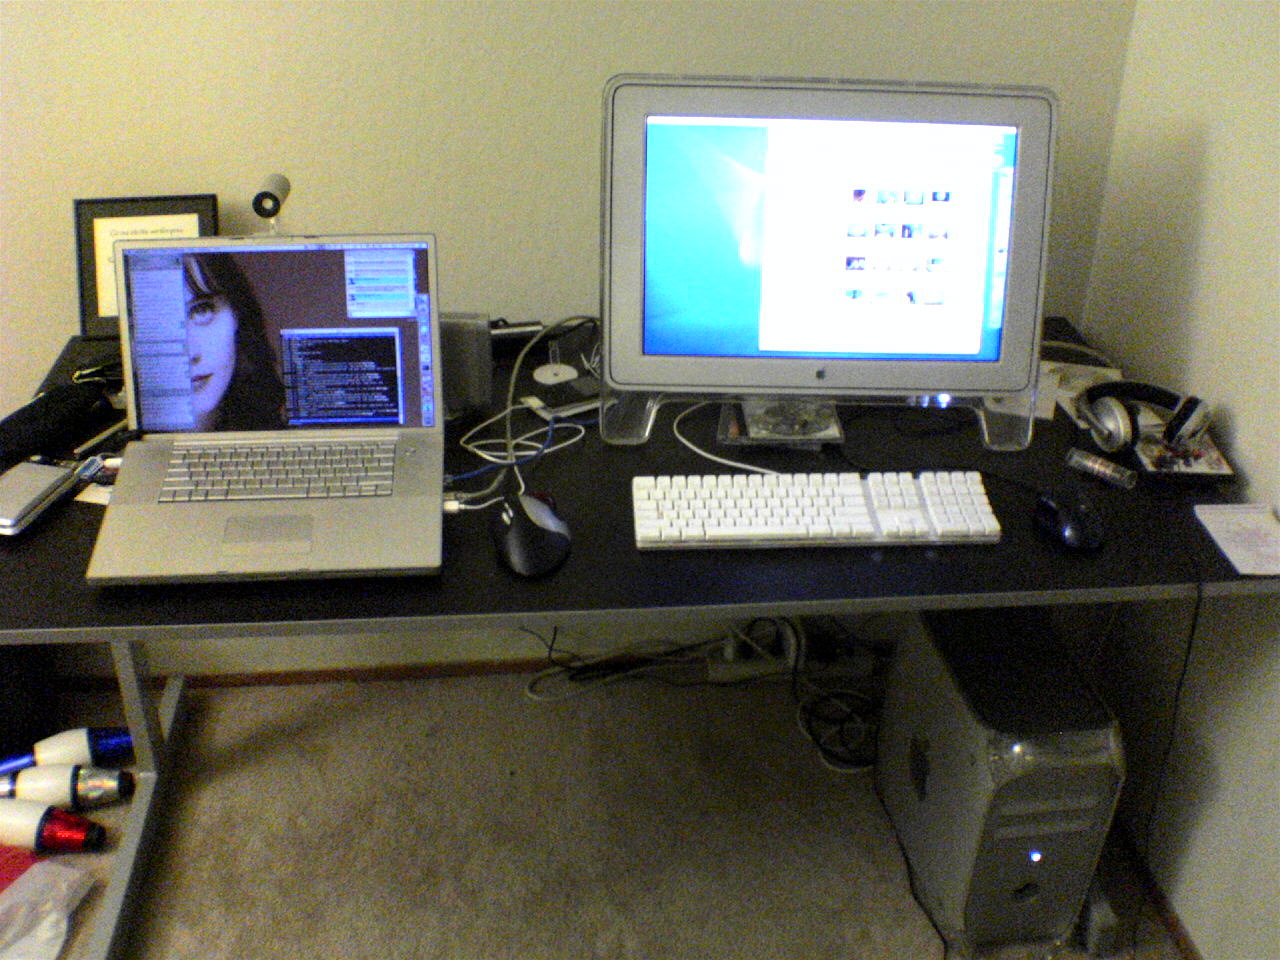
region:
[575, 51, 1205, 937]
old style desktop computer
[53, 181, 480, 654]
laptop on desk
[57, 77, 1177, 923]
laptop and desktop computers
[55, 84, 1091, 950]
laptop and desktop computers on desk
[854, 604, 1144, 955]
computer tower on floor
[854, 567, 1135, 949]
computer tower under table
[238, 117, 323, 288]
webcam hooked to laptop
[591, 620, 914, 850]
cords under table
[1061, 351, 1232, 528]
headphones on table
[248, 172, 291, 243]
the web cam is gray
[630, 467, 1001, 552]
the keyboard is white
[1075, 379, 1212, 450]
the headsets are gray and black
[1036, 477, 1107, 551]
the mouse is black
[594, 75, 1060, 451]
the monitor is white with clear plastic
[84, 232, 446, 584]
the laptop is gray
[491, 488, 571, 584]
the mouse is black and gray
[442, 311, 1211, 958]
the wires are multi colored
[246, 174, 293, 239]
Webcam attached to the laptop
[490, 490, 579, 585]
Gray and black mouse next to the laptop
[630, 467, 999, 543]
White keyboard in front of the monitor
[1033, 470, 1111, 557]
Black mouse next to the keyboard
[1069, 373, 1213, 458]
Gray headphones next to the monitor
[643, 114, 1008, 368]
Screen on the monitor is lit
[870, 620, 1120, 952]
Gray PC unit under the desk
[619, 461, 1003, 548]
White keyboard on the desk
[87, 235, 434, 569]
a silver laptop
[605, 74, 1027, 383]
a computer screen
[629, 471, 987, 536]
a white keyboard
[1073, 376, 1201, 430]
headphones on the desk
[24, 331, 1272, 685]
a black desk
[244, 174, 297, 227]
a webcam on the laptop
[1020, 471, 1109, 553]
a computer mouse on the desk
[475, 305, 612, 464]
wires on the desk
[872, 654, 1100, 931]
a computer tower on the floor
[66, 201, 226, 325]
a picture on the wall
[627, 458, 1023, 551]
a keyboard that is white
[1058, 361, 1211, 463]
headphones that are silver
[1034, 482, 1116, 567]
a mouse that is black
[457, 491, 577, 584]
a mouse that is silver and black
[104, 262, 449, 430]
the screen of a laptop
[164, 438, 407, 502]
the keyboard of a laptop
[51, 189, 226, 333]
paper that is framed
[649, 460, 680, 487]
a key on a keyboard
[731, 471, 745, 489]
a key on a keyboard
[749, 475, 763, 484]
a key on a keyboard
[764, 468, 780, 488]
a key on a keyboard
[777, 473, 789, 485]
a key on a keyboard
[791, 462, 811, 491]
a key on a keyboard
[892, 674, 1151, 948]
cpu is on the floor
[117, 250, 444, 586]
the laptop is on the desk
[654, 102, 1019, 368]
the screen is on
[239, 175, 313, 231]
webcam is on the computer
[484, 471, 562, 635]
mouse is on the table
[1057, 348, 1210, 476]
piece of electrical equipment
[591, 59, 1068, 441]
piece of electrical equipment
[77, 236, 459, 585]
piece of electrical equipment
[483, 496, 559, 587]
piece of electrical equipment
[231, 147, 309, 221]
piece of electrical equipment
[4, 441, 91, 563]
piece of electrical equipment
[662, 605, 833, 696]
piece of electrical equipment